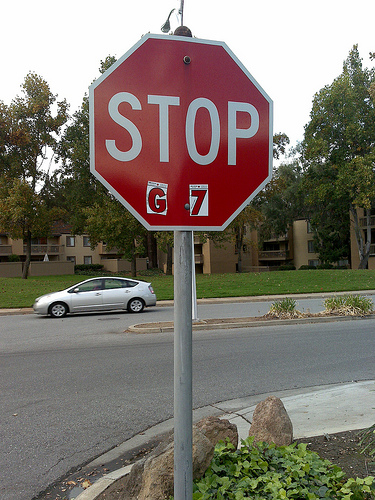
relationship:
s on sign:
[106, 84, 151, 174] [88, 31, 274, 231]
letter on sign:
[188, 97, 219, 165] [109, 38, 261, 182]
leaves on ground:
[198, 442, 308, 498] [204, 380, 374, 497]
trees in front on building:
[270, 71, 353, 191] [293, 186, 363, 277]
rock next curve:
[244, 383, 298, 461] [64, 412, 251, 499]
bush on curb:
[211, 431, 337, 498] [133, 420, 196, 466]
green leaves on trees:
[313, 135, 342, 155] [275, 68, 373, 243]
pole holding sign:
[172, 229, 193, 497] [88, 31, 274, 231]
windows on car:
[67, 278, 142, 289] [28, 272, 159, 323]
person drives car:
[89, 277, 105, 291] [23, 275, 171, 318]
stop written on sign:
[105, 86, 261, 167] [79, 44, 275, 495]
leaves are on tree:
[359, 166, 372, 197] [300, 44, 372, 230]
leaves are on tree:
[345, 98, 362, 131] [300, 44, 372, 230]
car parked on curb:
[31, 273, 156, 318] [3, 289, 370, 315]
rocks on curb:
[117, 396, 292, 498] [74, 380, 374, 497]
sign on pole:
[88, 31, 274, 231] [161, 227, 202, 498]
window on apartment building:
[65, 255, 76, 265] [0, 233, 171, 276]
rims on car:
[47, 299, 83, 321] [45, 260, 228, 340]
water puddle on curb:
[59, 485, 82, 495] [69, 459, 137, 498]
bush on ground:
[269, 299, 299, 319] [202, 308, 363, 327]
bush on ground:
[303, 282, 357, 336] [202, 308, 363, 327]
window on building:
[64, 229, 74, 252] [22, 209, 157, 281]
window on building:
[79, 235, 94, 252] [22, 209, 157, 281]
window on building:
[63, 252, 78, 265] [22, 209, 157, 281]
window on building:
[80, 250, 101, 269] [22, 209, 157, 281]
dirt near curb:
[296, 426, 373, 496] [217, 407, 253, 422]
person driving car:
[89, 277, 105, 291] [30, 268, 162, 325]